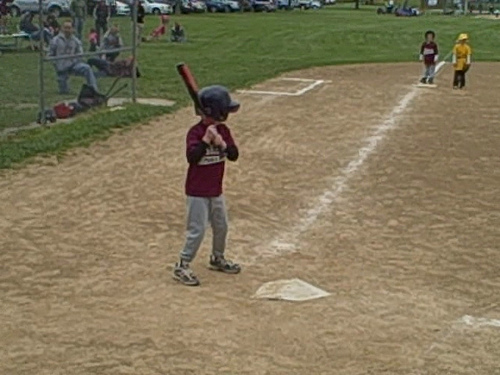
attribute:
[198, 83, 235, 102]
helmet — baseball, black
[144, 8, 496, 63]
grass — green , large section 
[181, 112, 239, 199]
shirt — red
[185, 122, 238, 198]
shirt — red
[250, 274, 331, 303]
base — white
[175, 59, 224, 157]
baseball — red, black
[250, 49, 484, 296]
line — long, white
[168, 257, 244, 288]
shoes — black and white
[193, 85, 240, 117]
helmet — black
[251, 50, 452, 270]
line — white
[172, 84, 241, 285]
boy — young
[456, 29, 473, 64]
hat —  yellow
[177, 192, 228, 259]
pants — grey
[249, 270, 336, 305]
home plate — white, dirty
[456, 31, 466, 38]
hat — yellow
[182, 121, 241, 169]
undershirt — black